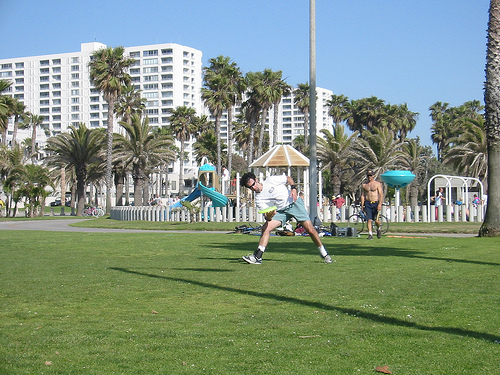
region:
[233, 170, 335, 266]
man playing with frisbee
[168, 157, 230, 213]
sliding board in playground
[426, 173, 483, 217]
swing set in playground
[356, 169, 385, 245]
man without shirt walking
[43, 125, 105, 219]
palm tree in background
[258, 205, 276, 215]
frisbee being caught by man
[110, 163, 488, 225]
playground surrounded by palm trees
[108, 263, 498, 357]
shadow of street light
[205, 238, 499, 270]
shadow of palm tree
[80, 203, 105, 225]
bicycle leaning against tree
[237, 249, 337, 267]
Man wearing shoes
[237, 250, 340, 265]
Man is wearing shoes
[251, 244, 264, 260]
Man wearing an ankle brace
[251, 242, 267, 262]
Man is wearing an ankle brace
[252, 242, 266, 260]
Man wearing a black ankle brace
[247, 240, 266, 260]
Man is wearing a black ankle brace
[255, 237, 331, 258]
Man is wearing socks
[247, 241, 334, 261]
Man wearing socks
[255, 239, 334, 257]
Man wearing white socks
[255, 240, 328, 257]
Man is wearing white socks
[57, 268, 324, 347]
grass is green in color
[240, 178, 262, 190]
man is wearing sunglasses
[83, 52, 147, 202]
palm trees in photo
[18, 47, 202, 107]
tall white building in photo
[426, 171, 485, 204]
white colored swingset in photo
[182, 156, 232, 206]
blue colored slides in park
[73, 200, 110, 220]
bicycles in background of photo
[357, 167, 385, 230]
man in background is shirtless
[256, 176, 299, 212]
man is wearing a white shirt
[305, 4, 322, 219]
gray metal pole in photo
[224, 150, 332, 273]
man bending over to catch frisbee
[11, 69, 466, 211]
mnany green palm trees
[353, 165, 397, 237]
man wearing blue shorts and no shirt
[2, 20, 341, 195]
two tall white buildings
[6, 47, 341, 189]
buildings with many windows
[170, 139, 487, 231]
children's playground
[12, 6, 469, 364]
photograph taken at a park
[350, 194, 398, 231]
bicycle behind man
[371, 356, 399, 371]
brown leaf on the green grass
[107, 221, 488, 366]
shadows on the green grass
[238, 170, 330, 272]
man catching a frisbee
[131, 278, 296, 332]
short green grass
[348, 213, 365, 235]
a bicycle wheel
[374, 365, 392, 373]
a leaf on the ground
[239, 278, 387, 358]
a shadow on the ground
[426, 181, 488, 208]
a group of people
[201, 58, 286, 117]
the tops of palm trees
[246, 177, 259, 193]
black sunglasses on the mans face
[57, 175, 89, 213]
trunks of palm trees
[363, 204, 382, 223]
a mans blue shorts